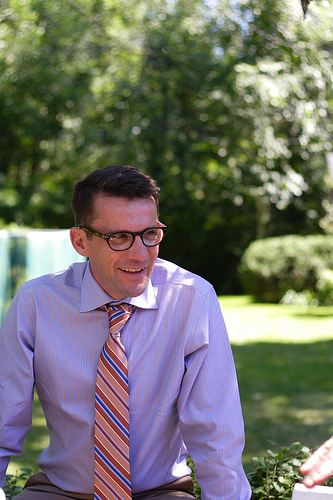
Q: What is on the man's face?
A: Glasses.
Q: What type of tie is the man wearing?
A: Necktie.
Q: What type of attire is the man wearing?
A: Formal.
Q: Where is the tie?
A: Around the man's neck.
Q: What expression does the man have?
A: Smile.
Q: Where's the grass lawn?
A: Behind man.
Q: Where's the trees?
A: Behind man.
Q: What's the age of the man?
A: Middle aged.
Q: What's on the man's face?
A: Black glasses.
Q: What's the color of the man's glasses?
A: Black.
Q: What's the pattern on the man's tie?
A: Striped.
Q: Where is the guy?
A: Sitting.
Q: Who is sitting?
A: The guy.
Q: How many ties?
A: 1.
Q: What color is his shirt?
A: Purple.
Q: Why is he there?
A: To rest.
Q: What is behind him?
A: Trees.